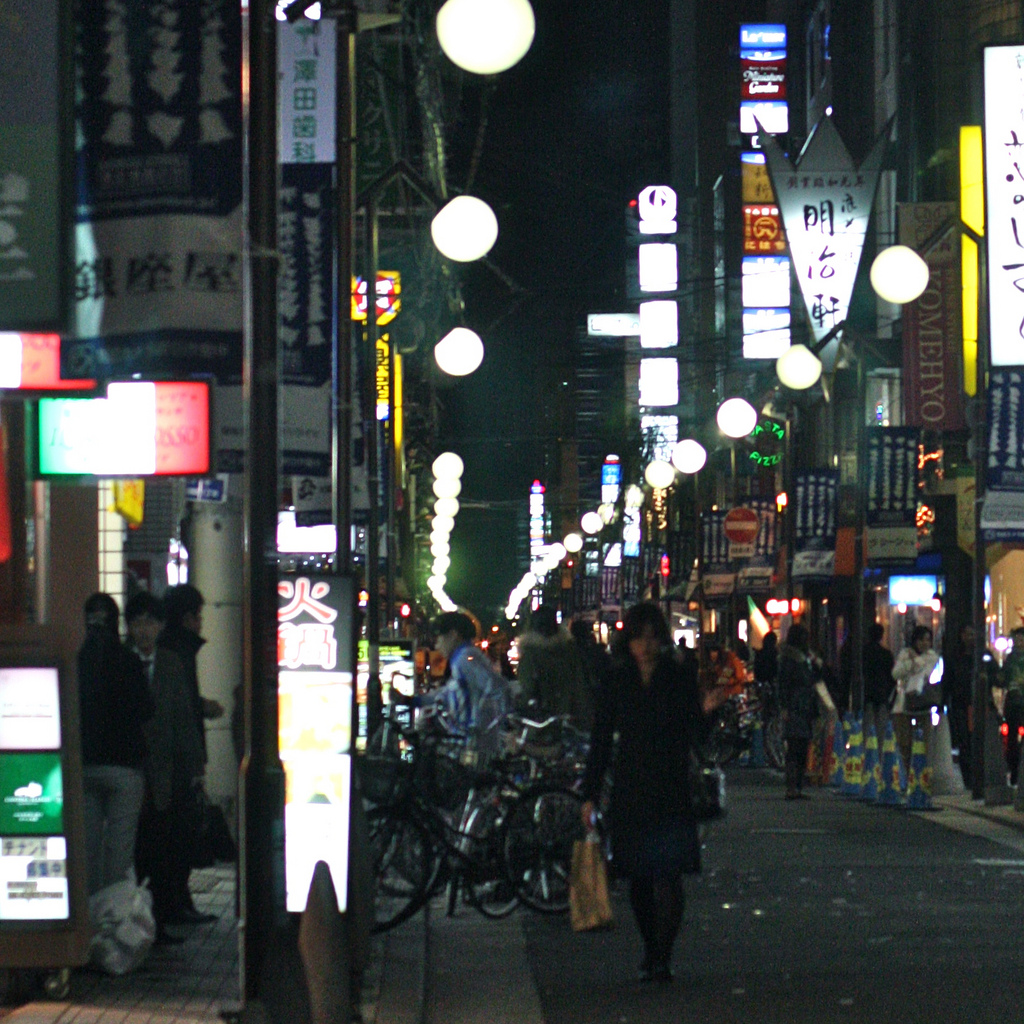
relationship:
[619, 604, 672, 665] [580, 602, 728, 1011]
head of woman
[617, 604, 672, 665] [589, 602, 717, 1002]
hair of woman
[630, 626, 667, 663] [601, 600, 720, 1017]
face of woman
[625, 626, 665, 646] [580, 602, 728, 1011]
eyes of woman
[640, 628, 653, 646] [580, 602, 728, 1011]
nose of woman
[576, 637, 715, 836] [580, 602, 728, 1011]
jacket of woman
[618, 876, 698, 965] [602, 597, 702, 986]
legs of a women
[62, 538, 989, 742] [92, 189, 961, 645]
people enjoying outdoors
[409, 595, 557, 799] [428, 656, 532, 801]
man wearing shirt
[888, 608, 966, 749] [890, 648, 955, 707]
person wearing shirt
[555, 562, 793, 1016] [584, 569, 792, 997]
woman wearing clothes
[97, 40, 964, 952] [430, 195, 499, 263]
view of light